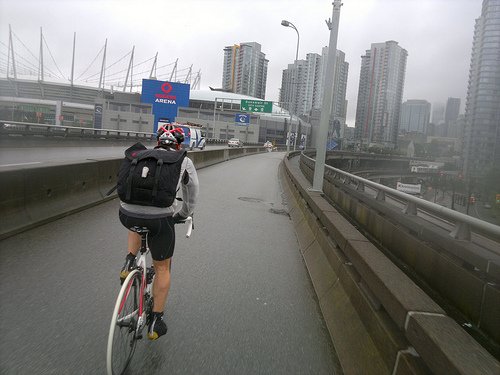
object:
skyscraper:
[450, 0, 499, 192]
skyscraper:
[354, 37, 408, 154]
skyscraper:
[439, 86, 462, 124]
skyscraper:
[222, 40, 269, 101]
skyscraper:
[276, 45, 348, 130]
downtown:
[5, 2, 495, 208]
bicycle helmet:
[155, 125, 184, 147]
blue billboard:
[136, 78, 192, 140]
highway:
[218, 145, 282, 265]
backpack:
[114, 142, 192, 209]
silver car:
[226, 137, 243, 147]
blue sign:
[229, 111, 259, 132]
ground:
[205, 223, 281, 336]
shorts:
[119, 212, 174, 259]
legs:
[123, 230, 173, 333]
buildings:
[214, 34, 411, 156]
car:
[214, 126, 253, 152]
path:
[2, 144, 348, 374]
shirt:
[118, 142, 201, 217]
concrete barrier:
[285, 172, 428, 361]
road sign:
[237, 99, 274, 116]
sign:
[88, 99, 109, 134]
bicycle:
[92, 209, 197, 368]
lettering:
[151, 90, 179, 105]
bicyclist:
[106, 117, 210, 344]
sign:
[238, 91, 276, 117]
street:
[0, 143, 231, 170]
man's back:
[119, 158, 182, 217]